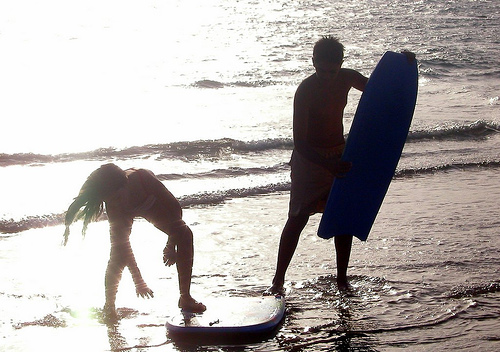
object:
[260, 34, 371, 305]
boy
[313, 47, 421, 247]
board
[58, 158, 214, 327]
girl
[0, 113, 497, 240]
waves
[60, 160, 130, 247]
hair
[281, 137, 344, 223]
shorts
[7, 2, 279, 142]
reflection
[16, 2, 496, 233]
water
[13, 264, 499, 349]
beach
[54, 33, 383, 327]
boy and girl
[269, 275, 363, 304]
feet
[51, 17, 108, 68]
bear